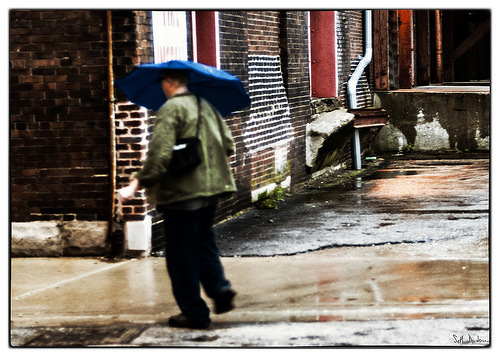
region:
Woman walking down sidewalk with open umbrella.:
[106, 43, 288, 335]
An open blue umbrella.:
[116, 52, 260, 119]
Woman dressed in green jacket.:
[140, 93, 247, 207]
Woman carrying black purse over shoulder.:
[159, 94, 203, 188]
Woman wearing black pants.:
[149, 194, 250, 317]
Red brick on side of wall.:
[36, 30, 100, 202]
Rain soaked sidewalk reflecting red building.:
[237, 253, 496, 330]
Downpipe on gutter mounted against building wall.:
[345, 16, 383, 173]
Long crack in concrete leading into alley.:
[255, 224, 466, 262]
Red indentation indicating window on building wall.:
[298, 14, 347, 103]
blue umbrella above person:
[130, 34, 270, 112]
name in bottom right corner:
[438, 318, 498, 355]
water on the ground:
[321, 248, 387, 309]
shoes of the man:
[163, 283, 251, 343]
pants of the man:
[153, 212, 257, 282]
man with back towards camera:
[118, 46, 286, 285]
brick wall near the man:
[255, 37, 303, 92]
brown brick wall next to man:
[21, 56, 93, 143]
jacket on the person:
[136, 93, 221, 176]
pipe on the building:
[338, 47, 384, 97]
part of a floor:
[383, 305, 412, 317]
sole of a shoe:
[217, 292, 235, 310]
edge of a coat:
[189, 167, 248, 214]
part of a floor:
[306, 277, 357, 334]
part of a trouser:
[155, 234, 207, 312]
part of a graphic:
[463, 330, 490, 344]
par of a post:
[346, 136, 364, 162]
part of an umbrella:
[195, 55, 238, 91]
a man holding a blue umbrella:
[117, 52, 251, 310]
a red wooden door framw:
[314, 17, 341, 94]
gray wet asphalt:
[261, 275, 373, 328]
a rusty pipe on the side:
[96, 21, 119, 236]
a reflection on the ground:
[294, 279, 344, 322]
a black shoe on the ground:
[166, 309, 223, 334]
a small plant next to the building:
[262, 185, 301, 210]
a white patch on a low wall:
[410, 122, 452, 150]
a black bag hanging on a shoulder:
[170, 138, 202, 178]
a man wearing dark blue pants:
[125, 55, 267, 327]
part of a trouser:
[168, 263, 192, 296]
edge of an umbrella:
[192, 57, 229, 89]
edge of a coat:
[205, 181, 235, 196]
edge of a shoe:
[205, 291, 241, 311]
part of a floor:
[368, 244, 410, 279]